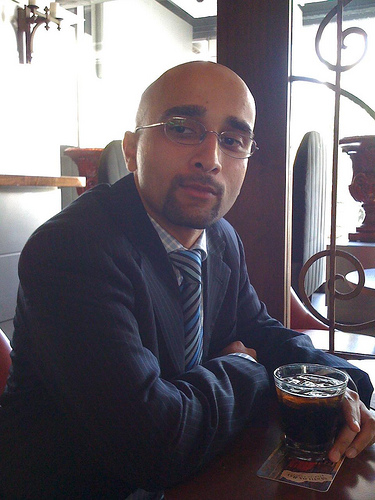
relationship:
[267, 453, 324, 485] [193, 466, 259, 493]
coaster on table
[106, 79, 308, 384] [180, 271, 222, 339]
man wearing tie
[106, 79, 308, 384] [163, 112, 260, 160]
man wearing glasses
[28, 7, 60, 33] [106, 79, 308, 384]
candles near man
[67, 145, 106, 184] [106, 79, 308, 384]
vase near man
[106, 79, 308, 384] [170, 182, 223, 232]
man has goatee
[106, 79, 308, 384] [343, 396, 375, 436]
man pointing finger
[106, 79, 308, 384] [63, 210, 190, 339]
man wearing suit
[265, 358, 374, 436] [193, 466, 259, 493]
drink on table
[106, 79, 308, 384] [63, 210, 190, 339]
man in suit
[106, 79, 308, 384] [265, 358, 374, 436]
man having a drink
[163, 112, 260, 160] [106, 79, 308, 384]
glasses on man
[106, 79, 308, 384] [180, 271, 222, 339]
man in tie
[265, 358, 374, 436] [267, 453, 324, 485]
drink on coaster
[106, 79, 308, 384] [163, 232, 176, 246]
man wearing shirt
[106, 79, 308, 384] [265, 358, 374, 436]
man holding drink